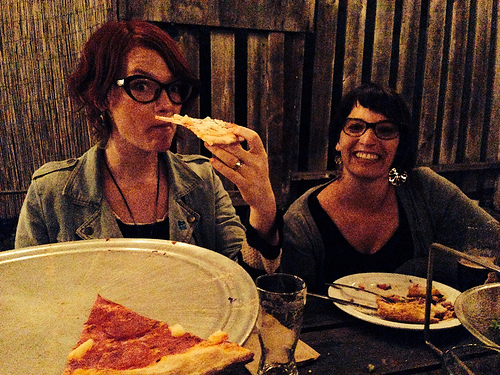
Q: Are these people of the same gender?
A: Yes, all the people are female.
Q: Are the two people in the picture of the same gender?
A: Yes, all the people are female.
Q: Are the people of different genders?
A: No, all the people are female.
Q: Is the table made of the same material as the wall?
A: Yes, both the table and the wall are made of wood.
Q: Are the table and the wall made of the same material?
A: Yes, both the table and the wall are made of wood.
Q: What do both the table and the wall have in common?
A: The material, both the table and the wall are wooden.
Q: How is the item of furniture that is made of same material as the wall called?
A: The piece of furniture is a table.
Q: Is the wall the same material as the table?
A: Yes, both the wall and the table are made of wood.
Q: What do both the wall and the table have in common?
A: The material, both the wall and the table are wooden.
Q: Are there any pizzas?
A: Yes, there is a pizza.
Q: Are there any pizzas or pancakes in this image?
A: Yes, there is a pizza.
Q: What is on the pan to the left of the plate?
A: The pizza is on the pan.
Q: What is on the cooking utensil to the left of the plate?
A: The pizza is on the pan.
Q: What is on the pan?
A: The pizza is on the pan.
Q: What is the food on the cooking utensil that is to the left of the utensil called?
A: The food is a pizza.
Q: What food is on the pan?
A: The food is a pizza.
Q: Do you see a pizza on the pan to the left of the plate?
A: Yes, there is a pizza on the pan.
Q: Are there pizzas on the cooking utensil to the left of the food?
A: Yes, there is a pizza on the pan.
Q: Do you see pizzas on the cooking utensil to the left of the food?
A: Yes, there is a pizza on the pan.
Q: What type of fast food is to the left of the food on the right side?
A: The food is a pizza.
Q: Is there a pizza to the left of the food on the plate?
A: Yes, there is a pizza to the left of the food.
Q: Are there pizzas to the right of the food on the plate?
A: No, the pizza is to the left of the food.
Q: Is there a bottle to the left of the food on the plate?
A: No, there is a pizza to the left of the food.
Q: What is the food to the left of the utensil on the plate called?
A: The food is a pizza.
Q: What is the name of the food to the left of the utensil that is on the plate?
A: The food is a pizza.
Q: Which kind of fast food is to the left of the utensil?
A: The food is a pizza.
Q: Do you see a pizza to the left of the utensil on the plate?
A: Yes, there is a pizza to the left of the utensil.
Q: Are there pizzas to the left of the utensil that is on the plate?
A: Yes, there is a pizza to the left of the utensil.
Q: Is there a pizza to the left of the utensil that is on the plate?
A: Yes, there is a pizza to the left of the utensil.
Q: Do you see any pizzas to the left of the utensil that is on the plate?
A: Yes, there is a pizza to the left of the utensil.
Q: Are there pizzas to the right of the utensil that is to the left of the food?
A: No, the pizza is to the left of the utensil.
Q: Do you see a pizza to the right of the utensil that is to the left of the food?
A: No, the pizza is to the left of the utensil.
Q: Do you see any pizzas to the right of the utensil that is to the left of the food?
A: No, the pizza is to the left of the utensil.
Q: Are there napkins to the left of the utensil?
A: No, there is a pizza to the left of the utensil.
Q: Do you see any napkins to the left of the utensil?
A: No, there is a pizza to the left of the utensil.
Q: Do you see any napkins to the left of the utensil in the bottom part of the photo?
A: No, there is a pizza to the left of the utensil.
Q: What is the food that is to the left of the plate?
A: The food is a pizza.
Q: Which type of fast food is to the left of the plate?
A: The food is a pizza.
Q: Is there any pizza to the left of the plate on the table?
A: Yes, there is a pizza to the left of the plate.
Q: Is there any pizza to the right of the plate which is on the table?
A: No, the pizza is to the left of the plate.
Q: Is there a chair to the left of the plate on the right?
A: No, there is a pizza to the left of the plate.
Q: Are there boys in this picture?
A: No, there are no boys.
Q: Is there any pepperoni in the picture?
A: Yes, there is pepperoni.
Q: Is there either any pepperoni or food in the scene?
A: Yes, there is pepperoni.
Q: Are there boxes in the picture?
A: No, there are no boxes.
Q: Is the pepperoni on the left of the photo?
A: Yes, the pepperoni is on the left of the image.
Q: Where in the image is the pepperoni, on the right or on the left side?
A: The pepperoni is on the left of the image.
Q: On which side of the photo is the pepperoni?
A: The pepperoni is on the left of the image.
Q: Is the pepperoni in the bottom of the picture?
A: Yes, the pepperoni is in the bottom of the image.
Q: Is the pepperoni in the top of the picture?
A: No, the pepperoni is in the bottom of the image.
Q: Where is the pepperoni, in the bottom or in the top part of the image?
A: The pepperoni is in the bottom of the image.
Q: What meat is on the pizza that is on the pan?
A: The meat is pepperoni.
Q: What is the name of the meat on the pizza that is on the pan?
A: The meat is pepperoni.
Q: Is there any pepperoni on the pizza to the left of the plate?
A: Yes, there is pepperoni on the pizza.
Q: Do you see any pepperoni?
A: Yes, there is pepperoni.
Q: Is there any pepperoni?
A: Yes, there is pepperoni.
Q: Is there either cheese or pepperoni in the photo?
A: Yes, there is pepperoni.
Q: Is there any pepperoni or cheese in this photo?
A: Yes, there is pepperoni.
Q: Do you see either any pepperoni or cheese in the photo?
A: Yes, there is pepperoni.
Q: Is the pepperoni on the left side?
A: Yes, the pepperoni is on the left of the image.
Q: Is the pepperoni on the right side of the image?
A: No, the pepperoni is on the left of the image.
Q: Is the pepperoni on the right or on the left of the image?
A: The pepperoni is on the left of the image.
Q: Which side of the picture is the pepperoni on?
A: The pepperoni is on the left of the image.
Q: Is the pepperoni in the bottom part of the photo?
A: Yes, the pepperoni is in the bottom of the image.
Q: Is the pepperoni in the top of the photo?
A: No, the pepperoni is in the bottom of the image.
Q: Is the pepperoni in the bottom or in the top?
A: The pepperoni is in the bottom of the image.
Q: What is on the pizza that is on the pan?
A: The pepperoni is on the pizza.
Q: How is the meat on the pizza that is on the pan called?
A: The meat is pepperoni.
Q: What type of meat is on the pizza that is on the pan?
A: The meat is pepperoni.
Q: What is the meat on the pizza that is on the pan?
A: The meat is pepperoni.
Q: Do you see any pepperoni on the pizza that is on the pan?
A: Yes, there is pepperoni on the pizza.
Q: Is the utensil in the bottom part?
A: Yes, the utensil is in the bottom of the image.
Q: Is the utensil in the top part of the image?
A: No, the utensil is in the bottom of the image.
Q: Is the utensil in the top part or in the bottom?
A: The utensil is in the bottom of the image.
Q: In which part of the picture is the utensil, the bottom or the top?
A: The utensil is in the bottom of the image.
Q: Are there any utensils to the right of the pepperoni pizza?
A: Yes, there is a utensil to the right of the pizza.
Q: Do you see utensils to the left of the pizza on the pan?
A: No, the utensil is to the right of the pizza.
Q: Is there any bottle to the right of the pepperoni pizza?
A: No, there is a utensil to the right of the pizza.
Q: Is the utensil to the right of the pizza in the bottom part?
A: Yes, the utensil is to the right of the pizza.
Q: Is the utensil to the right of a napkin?
A: No, the utensil is to the right of the pizza.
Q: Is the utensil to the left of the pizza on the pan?
A: No, the utensil is to the right of the pizza.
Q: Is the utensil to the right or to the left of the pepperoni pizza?
A: The utensil is to the right of the pizza.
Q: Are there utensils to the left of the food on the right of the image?
A: Yes, there is a utensil to the left of the food.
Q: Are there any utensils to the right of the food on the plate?
A: No, the utensil is to the left of the food.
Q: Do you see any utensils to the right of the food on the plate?
A: No, the utensil is to the left of the food.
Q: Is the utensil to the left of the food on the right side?
A: Yes, the utensil is to the left of the food.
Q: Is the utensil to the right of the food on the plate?
A: No, the utensil is to the left of the food.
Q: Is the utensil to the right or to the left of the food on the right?
A: The utensil is to the left of the food.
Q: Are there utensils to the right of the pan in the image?
A: Yes, there is a utensil to the right of the pan.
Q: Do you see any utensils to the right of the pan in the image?
A: Yes, there is a utensil to the right of the pan.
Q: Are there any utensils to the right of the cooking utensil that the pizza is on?
A: Yes, there is a utensil to the right of the pan.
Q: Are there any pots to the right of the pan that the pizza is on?
A: No, there is a utensil to the right of the pan.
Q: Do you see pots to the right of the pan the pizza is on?
A: No, there is a utensil to the right of the pan.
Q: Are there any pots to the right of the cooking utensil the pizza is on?
A: No, there is a utensil to the right of the pan.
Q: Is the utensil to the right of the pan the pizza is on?
A: Yes, the utensil is to the right of the pan.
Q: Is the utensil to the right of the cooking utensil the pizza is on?
A: Yes, the utensil is to the right of the pan.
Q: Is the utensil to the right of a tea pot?
A: No, the utensil is to the right of the pan.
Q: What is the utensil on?
A: The utensil is on the plate.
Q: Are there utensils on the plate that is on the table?
A: Yes, there is a utensil on the plate.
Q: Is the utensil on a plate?
A: Yes, the utensil is on a plate.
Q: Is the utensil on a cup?
A: No, the utensil is on a plate.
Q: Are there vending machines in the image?
A: No, there are no vending machines.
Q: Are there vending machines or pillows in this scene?
A: No, there are no vending machines or pillows.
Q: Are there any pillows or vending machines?
A: No, there are no vending machines or pillows.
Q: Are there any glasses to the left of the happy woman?
A: Yes, there are glasses to the left of the woman.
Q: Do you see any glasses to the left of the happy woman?
A: Yes, there are glasses to the left of the woman.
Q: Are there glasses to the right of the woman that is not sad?
A: No, the glasses are to the left of the woman.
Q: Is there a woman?
A: Yes, there is a woman.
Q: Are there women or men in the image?
A: Yes, there is a woman.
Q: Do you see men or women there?
A: Yes, there is a woman.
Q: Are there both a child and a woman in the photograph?
A: No, there is a woman but no children.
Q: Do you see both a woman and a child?
A: No, there is a woman but no children.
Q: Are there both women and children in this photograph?
A: No, there is a woman but no children.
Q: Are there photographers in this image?
A: No, there are no photographers.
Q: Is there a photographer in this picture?
A: No, there are no photographers.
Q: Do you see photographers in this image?
A: No, there are no photographers.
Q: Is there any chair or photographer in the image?
A: No, there are no photographers or chairs.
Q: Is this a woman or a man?
A: This is a woman.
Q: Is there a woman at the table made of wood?
A: Yes, there is a woman at the table.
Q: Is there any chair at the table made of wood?
A: No, there is a woman at the table.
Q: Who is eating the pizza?
A: The woman is eating the pizza.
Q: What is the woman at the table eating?
A: The woman is eating a pizza.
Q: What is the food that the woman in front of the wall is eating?
A: The food is a pizza.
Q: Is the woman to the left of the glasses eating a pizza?
A: Yes, the woman is eating a pizza.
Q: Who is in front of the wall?
A: The woman is in front of the wall.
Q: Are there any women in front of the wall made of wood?
A: Yes, there is a woman in front of the wall.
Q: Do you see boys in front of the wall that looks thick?
A: No, there is a woman in front of the wall.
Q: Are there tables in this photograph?
A: Yes, there is a table.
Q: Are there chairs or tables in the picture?
A: Yes, there is a table.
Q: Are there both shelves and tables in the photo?
A: No, there is a table but no shelves.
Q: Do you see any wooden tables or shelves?
A: Yes, there is a wood table.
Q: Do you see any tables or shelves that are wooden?
A: Yes, the table is wooden.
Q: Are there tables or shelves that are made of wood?
A: Yes, the table is made of wood.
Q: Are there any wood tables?
A: Yes, there is a table that is made of wood.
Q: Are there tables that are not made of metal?
A: Yes, there is a table that is made of wood.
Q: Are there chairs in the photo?
A: No, there are no chairs.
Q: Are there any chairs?
A: No, there are no chairs.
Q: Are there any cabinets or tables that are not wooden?
A: No, there is a table but it is wooden.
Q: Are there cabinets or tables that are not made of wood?
A: No, there is a table but it is made of wood.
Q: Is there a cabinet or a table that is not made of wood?
A: No, there is a table but it is made of wood.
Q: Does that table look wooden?
A: Yes, the table is wooden.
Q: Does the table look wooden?
A: Yes, the table is wooden.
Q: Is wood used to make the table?
A: Yes, the table is made of wood.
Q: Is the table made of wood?
A: Yes, the table is made of wood.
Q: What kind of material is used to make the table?
A: The table is made of wood.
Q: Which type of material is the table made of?
A: The table is made of wood.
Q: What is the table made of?
A: The table is made of wood.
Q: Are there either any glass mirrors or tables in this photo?
A: No, there is a table but it is wooden.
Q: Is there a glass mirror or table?
A: No, there is a table but it is wooden.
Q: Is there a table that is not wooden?
A: No, there is a table but it is wooden.